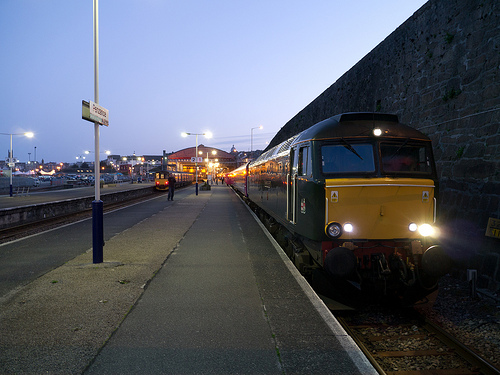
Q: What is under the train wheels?
A: Train tracks.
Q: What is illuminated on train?
A: Lights.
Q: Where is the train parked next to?
A: A platform.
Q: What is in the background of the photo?
A: Cityscape.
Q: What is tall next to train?
A: Stone wall.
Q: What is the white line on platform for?
A: Safety.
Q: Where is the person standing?
A: By platform.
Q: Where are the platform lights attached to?
A: Metal poles.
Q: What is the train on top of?
A: Tracks.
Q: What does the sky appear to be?
A: Clear and blue.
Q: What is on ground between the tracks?
A: Gravel.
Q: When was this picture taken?
A: Sunrise.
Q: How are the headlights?
A: Lit.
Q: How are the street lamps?
A: On.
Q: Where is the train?
A: On the tracks.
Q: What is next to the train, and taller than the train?
A: A wall.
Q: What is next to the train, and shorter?
A: A sidewalk.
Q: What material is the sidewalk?
A: Concrete.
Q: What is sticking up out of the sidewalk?
A: A pole.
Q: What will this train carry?
A: Passengers.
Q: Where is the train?
A: On the tracks.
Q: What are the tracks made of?
A: Metal.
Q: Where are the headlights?
A: On the front of the train.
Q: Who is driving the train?
A: A conductor.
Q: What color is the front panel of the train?
A: Yellow.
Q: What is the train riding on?
A: Rails.